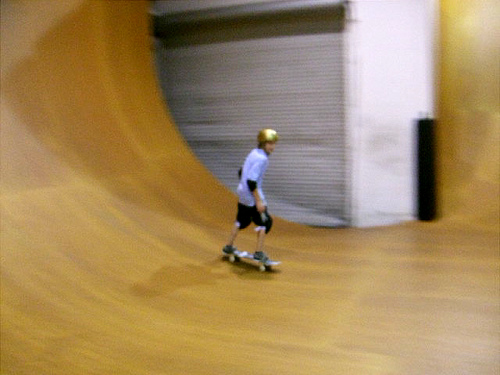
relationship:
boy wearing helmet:
[217, 120, 292, 273] [248, 122, 281, 150]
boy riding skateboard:
[217, 120, 292, 273] [220, 244, 283, 276]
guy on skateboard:
[217, 120, 292, 273] [220, 244, 283, 276]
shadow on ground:
[124, 238, 227, 306] [9, 219, 498, 370]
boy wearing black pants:
[217, 120, 292, 273] [228, 202, 276, 234]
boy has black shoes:
[217, 120, 292, 273] [221, 245, 275, 265]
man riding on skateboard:
[217, 120, 292, 273] [220, 244, 283, 276]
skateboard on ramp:
[220, 244, 283, 276] [8, 0, 321, 375]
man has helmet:
[217, 120, 292, 273] [248, 122, 281, 150]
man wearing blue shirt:
[217, 120, 292, 273] [228, 146, 278, 209]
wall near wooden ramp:
[159, 8, 447, 218] [3, 0, 495, 364]